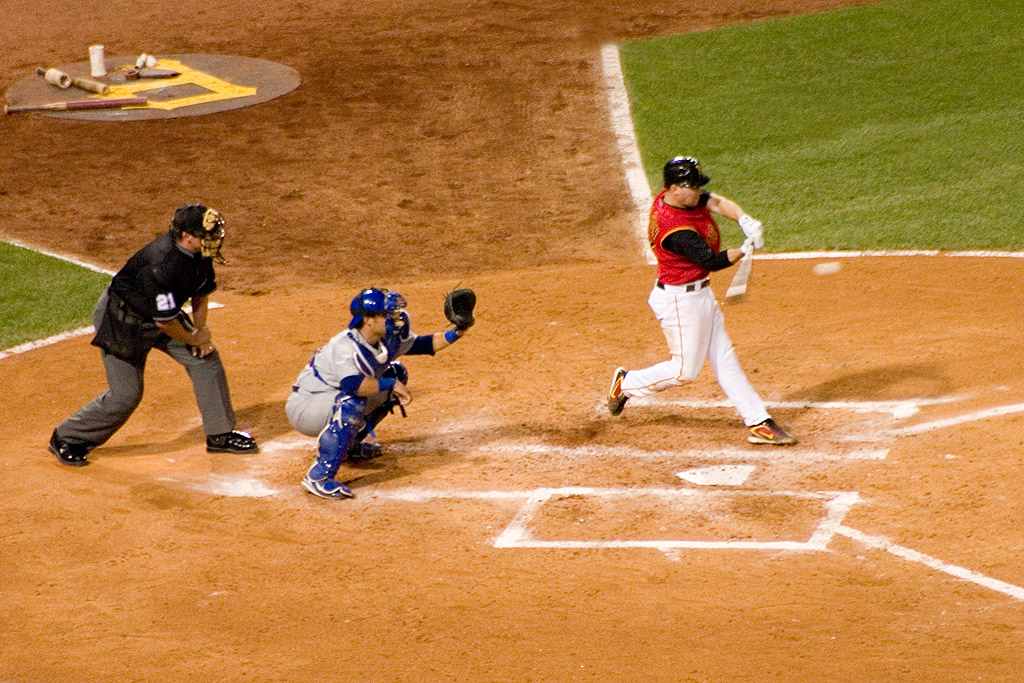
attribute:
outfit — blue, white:
[286, 286, 480, 477]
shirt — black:
[114, 235, 214, 330]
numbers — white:
[144, 282, 187, 315]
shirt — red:
[638, 200, 734, 286]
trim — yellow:
[663, 216, 703, 249]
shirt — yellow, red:
[634, 200, 742, 300]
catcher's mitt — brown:
[432, 279, 487, 338]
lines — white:
[588, 35, 681, 245]